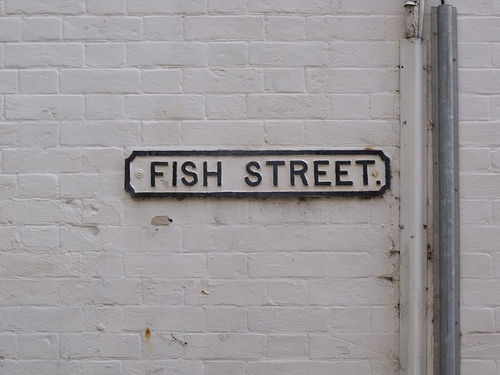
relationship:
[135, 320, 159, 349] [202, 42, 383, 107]
spot on wall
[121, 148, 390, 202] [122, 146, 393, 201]
black border has border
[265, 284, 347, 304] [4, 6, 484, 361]
brick on wall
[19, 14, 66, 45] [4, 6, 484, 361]
brick on wall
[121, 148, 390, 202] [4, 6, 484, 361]
black border on wall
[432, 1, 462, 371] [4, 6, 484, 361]
pipe on wall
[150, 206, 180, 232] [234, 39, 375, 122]
chip on wall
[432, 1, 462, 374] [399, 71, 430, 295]
pipe near pipe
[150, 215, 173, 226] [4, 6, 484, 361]
chip on wall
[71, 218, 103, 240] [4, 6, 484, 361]
peeling paint on wall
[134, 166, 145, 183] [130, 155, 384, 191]
white screw on white sign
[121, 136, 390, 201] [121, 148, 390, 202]
black border on black border